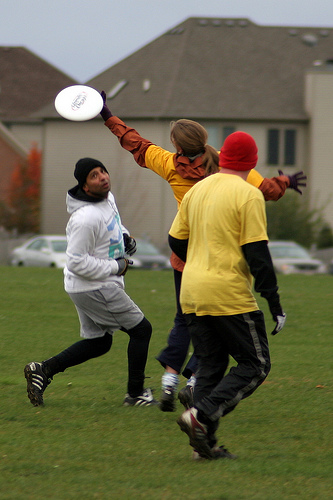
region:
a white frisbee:
[56, 85, 103, 117]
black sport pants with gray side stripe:
[184, 312, 272, 423]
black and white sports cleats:
[23, 363, 160, 409]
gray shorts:
[65, 282, 144, 339]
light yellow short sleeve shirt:
[168, 172, 266, 316]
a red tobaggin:
[220, 130, 259, 169]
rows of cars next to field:
[12, 234, 328, 275]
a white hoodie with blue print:
[65, 187, 125, 289]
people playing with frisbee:
[22, 84, 309, 459]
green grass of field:
[1, 266, 330, 498]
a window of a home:
[269, 126, 295, 164]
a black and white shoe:
[25, 358, 46, 405]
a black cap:
[69, 156, 104, 185]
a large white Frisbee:
[52, 85, 104, 122]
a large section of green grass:
[2, 261, 331, 498]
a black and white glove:
[271, 313, 287, 336]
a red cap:
[219, 131, 259, 170]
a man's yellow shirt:
[168, 170, 269, 318]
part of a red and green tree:
[6, 141, 47, 227]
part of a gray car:
[10, 235, 69, 272]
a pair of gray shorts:
[68, 286, 146, 339]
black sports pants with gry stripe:
[183, 309, 271, 435]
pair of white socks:
[162, 371, 201, 388]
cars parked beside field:
[10, 231, 325, 276]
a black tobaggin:
[74, 159, 108, 181]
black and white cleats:
[22, 361, 156, 396]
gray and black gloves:
[117, 235, 138, 274]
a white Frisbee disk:
[53, 83, 102, 121]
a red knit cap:
[218, 129, 258, 173]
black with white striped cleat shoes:
[23, 361, 50, 408]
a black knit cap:
[72, 156, 109, 190]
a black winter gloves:
[277, 167, 307, 196]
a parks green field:
[285, 274, 332, 499]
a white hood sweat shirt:
[64, 185, 126, 289]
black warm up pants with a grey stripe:
[183, 310, 271, 422]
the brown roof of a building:
[126, 15, 331, 120]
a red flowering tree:
[0, 139, 40, 229]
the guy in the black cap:
[51, 156, 147, 403]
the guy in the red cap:
[178, 131, 264, 424]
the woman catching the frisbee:
[133, 143, 230, 285]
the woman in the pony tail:
[155, 122, 220, 183]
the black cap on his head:
[72, 156, 107, 185]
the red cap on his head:
[209, 131, 268, 179]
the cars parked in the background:
[22, 222, 311, 280]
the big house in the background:
[57, 7, 328, 258]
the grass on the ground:
[11, 274, 312, 491]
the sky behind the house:
[9, 4, 331, 60]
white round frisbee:
[51, 83, 103, 121]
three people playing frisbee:
[24, 80, 300, 460]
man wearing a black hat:
[68, 157, 114, 199]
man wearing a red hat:
[165, 129, 284, 464]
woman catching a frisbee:
[53, 82, 217, 174]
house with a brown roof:
[0, 13, 331, 244]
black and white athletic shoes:
[23, 361, 159, 409]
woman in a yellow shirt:
[100, 90, 307, 202]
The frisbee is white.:
[54, 86, 104, 115]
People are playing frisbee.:
[55, 160, 277, 378]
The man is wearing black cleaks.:
[18, 358, 155, 419]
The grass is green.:
[32, 412, 307, 497]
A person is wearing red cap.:
[217, 135, 262, 166]